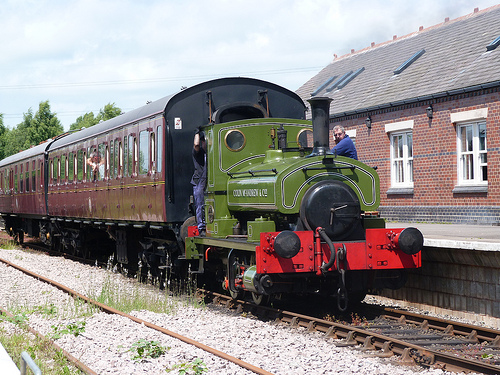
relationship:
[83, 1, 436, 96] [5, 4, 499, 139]
clouds in sky